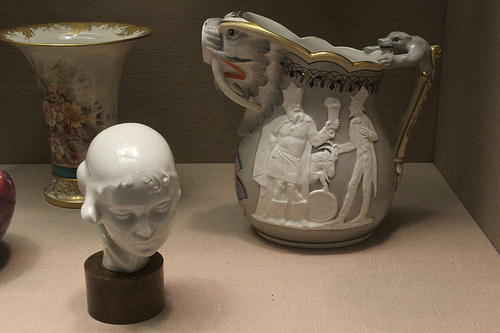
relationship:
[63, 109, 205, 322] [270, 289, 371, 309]
bust on table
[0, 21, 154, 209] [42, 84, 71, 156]
vase with flowers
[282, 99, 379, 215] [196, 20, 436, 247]
men on vase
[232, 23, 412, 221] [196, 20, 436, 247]
design on vase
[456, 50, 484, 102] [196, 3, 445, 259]
wall behind pitcher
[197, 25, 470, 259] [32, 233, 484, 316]
pitcher on display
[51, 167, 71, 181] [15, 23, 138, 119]
band at bottom vase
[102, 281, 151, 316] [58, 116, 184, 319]
base of statue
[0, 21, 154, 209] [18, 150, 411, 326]
vase on table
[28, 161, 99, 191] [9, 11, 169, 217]
stripe on vase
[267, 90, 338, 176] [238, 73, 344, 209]
man on surface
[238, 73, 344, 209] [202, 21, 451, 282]
surface of vase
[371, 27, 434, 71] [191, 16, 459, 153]
monster sculpted into vase handle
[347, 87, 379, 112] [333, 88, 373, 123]
hat on man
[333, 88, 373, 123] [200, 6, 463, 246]
man on vase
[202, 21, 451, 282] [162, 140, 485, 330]
vase on table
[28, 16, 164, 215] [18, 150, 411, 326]
vase on table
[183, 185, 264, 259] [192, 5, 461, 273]
shadow of vase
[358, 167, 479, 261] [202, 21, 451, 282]
shadow of vase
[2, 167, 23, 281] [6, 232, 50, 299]
shadow of vase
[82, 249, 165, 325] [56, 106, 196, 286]
base of a statue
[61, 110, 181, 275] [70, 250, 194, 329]
head on a base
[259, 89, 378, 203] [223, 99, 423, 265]
two white carvings on side of a pitcher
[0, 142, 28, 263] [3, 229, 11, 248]
part of a red vase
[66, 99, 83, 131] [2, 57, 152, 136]
old white and gold vase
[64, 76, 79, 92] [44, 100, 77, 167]
flower painted on vase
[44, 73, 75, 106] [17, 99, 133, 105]
flower painted on vase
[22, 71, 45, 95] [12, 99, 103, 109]
flower painted on vase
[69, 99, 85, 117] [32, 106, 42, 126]
flower painted on vase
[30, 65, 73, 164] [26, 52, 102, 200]
flowers on vase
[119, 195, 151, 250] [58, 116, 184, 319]
mouth of statue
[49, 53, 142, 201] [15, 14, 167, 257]
paintings on vase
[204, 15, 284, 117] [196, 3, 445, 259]
head carved into pitcher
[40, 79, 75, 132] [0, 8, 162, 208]
flower on vase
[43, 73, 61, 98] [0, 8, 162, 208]
flower on vase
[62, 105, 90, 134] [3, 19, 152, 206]
flower on vase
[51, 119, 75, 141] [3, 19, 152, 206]
flower on vase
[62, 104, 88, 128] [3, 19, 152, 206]
flower on vase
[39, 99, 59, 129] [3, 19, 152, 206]
flower painted on vase